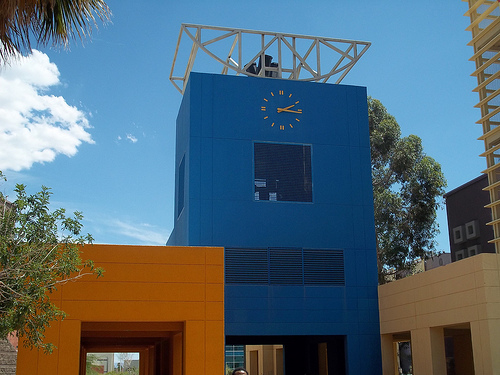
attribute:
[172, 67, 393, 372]
pillar — blue, beautiful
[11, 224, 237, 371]
building — orange , deep gold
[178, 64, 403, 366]
wall — dark blue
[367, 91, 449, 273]
tree — short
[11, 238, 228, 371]
building — yellow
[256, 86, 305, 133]
clock — small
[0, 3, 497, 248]
sky — clear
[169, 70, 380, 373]
building — blue 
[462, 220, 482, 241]
window — white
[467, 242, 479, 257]
window — white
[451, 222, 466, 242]
window — white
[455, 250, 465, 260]
window — white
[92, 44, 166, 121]
sky — blue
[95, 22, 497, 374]
building — blue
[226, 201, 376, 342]
wall — blue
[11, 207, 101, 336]
branches — thin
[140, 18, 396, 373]
building — blue 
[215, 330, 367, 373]
opening — large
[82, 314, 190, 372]
opening — large